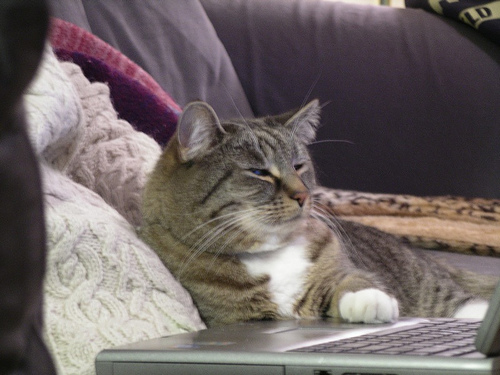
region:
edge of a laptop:
[364, 328, 381, 346]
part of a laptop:
[196, 360, 208, 365]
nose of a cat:
[276, 130, 299, 232]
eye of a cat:
[248, 150, 268, 187]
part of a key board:
[363, 341, 368, 355]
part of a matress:
[401, 194, 414, 199]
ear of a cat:
[207, 170, 221, 207]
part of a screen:
[481, 308, 491, 327]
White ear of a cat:
[154, 90, 235, 172]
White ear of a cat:
[272, 98, 342, 155]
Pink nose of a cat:
[285, 176, 315, 216]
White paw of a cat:
[323, 264, 436, 343]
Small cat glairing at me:
[145, 82, 355, 259]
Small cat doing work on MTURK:
[107, 83, 442, 370]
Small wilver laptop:
[114, 291, 476, 373]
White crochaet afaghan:
[38, 103, 136, 325]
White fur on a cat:
[235, 245, 315, 300]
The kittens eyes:
[228, 155, 317, 185]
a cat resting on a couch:
[138, 102, 498, 324]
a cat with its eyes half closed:
[238, 155, 310, 186]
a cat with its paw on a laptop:
[331, 276, 401, 323]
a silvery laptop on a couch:
[91, 274, 498, 372]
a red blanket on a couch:
[48, 18, 188, 143]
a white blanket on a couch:
[15, 43, 205, 373]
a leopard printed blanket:
[321, 185, 498, 255]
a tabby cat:
[147, 100, 497, 327]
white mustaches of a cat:
[163, 197, 367, 280]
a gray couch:
[50, 2, 495, 198]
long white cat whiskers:
[180, 197, 292, 284]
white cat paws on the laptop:
[338, 287, 400, 327]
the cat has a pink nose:
[291, 188, 310, 205]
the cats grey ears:
[174, 99, 231, 160]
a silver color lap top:
[94, 322, 498, 374]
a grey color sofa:
[185, 0, 495, 95]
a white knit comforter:
[25, 45, 155, 347]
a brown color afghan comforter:
[333, 167, 496, 243]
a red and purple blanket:
[51, 14, 175, 141]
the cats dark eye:
[248, 166, 271, 178]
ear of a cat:
[167, 100, 232, 156]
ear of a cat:
[268, 95, 330, 140]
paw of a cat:
[334, 285, 406, 321]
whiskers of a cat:
[162, 193, 279, 281]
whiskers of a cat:
[309, 189, 359, 259]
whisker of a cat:
[215, 78, 260, 144]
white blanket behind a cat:
[14, 39, 216, 373]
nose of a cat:
[285, 182, 312, 209]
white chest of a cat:
[245, 238, 320, 310]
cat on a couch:
[117, 95, 499, 335]